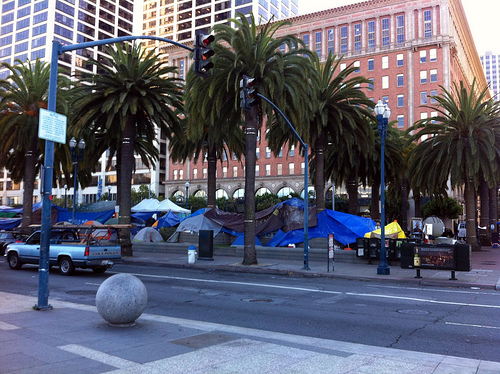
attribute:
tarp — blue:
[230, 199, 377, 249]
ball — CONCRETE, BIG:
[88, 260, 162, 333]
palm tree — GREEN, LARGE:
[185, 14, 317, 278]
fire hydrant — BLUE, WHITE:
[184, 244, 201, 266]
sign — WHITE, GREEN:
[37, 106, 67, 144]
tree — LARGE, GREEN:
[407, 77, 498, 263]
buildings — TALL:
[0, 2, 498, 231]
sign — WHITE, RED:
[328, 235, 335, 276]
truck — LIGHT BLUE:
[4, 227, 121, 273]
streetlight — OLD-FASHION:
[368, 96, 400, 281]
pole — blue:
[299, 151, 314, 270]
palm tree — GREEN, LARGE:
[400, 77, 497, 258]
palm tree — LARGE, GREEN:
[172, 28, 329, 288]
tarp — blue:
[266, 177, 421, 274]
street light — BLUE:
[373, 97, 391, 275]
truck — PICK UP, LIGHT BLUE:
[6, 221, 128, 273]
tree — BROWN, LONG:
[185, 11, 317, 261]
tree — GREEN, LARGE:
[159, 7, 304, 259]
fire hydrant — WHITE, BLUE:
[184, 242, 199, 265]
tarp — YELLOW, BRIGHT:
[361, 205, 406, 242]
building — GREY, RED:
[151, 0, 496, 245]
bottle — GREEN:
[407, 246, 424, 268]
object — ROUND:
[94, 269, 148, 330]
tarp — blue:
[313, 205, 374, 244]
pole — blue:
[33, 35, 64, 315]